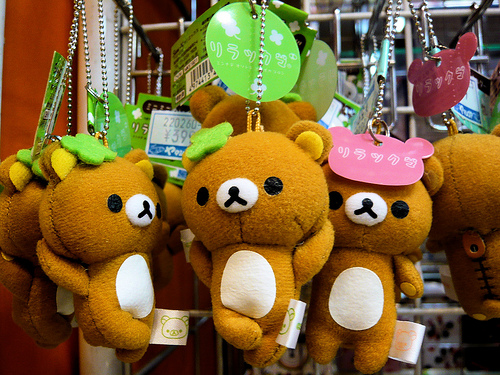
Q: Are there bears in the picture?
A: Yes, there is a bear.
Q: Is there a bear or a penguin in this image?
A: Yes, there is a bear.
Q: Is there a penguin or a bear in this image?
A: Yes, there is a bear.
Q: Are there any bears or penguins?
A: Yes, there is a bear.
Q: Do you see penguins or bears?
A: Yes, there is a bear.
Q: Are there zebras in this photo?
A: No, there are no zebras.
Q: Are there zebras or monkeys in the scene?
A: No, there are no zebras or monkeys.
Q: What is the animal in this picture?
A: The animal is a bear.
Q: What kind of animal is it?
A: The animal is a bear.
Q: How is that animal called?
A: This is a bear.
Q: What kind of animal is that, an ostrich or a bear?
A: This is a bear.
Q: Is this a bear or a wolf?
A: This is a bear.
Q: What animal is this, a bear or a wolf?
A: This is a bear.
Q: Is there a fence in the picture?
A: No, there are no fences.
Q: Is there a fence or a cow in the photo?
A: No, there are no fences or cows.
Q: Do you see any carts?
A: No, there are no carts.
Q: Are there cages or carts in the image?
A: No, there are no carts or cages.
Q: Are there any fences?
A: No, there are no fences.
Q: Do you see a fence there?
A: No, there are no fences.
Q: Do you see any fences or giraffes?
A: No, there are no fences or giraffes.